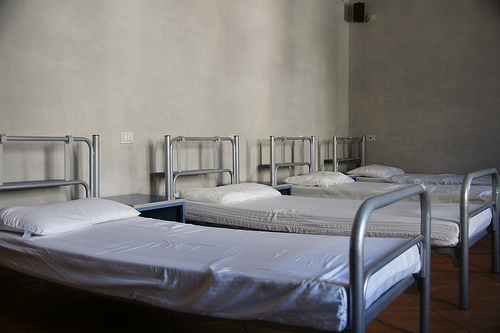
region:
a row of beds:
[25, 89, 476, 331]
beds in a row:
[62, 89, 494, 311]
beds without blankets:
[84, 124, 457, 331]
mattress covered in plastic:
[114, 99, 498, 291]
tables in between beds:
[29, 82, 496, 271]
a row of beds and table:
[89, 104, 462, 329]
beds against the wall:
[76, 106, 499, 323]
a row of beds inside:
[76, 71, 493, 331]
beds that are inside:
[85, 115, 499, 306]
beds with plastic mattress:
[84, 99, 498, 299]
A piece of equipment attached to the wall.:
[341, 0, 386, 26]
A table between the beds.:
[101, 177, 198, 228]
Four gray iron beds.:
[1, 128, 496, 332]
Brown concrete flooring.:
[382, 218, 499, 331]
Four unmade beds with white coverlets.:
[3, 205, 425, 325]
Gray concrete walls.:
[1, 2, 498, 139]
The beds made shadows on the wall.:
[4, 130, 377, 205]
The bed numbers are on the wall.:
[118, 125, 138, 150]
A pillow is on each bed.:
[2, 144, 411, 238]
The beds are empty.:
[4, 143, 494, 298]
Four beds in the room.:
[81, 137, 488, 303]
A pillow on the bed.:
[20, 192, 100, 229]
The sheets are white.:
[137, 228, 350, 331]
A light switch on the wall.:
[115, 112, 141, 162]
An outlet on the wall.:
[353, 134, 380, 156]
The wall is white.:
[98, 23, 335, 116]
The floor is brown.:
[403, 282, 488, 329]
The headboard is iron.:
[3, 138, 140, 190]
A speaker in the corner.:
[339, 4, 362, 21]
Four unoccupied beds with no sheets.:
[4, 84, 487, 312]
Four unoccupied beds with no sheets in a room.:
[0, 85, 487, 310]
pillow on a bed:
[16, 196, 144, 238]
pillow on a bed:
[207, 175, 293, 210]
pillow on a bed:
[310, 152, 345, 192]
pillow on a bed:
[357, 153, 408, 186]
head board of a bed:
[6, 123, 107, 189]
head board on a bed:
[161, 128, 251, 178]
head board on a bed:
[265, 125, 326, 171]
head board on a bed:
[327, 128, 367, 163]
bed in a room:
[310, 170, 448, 297]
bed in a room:
[452, 157, 497, 219]